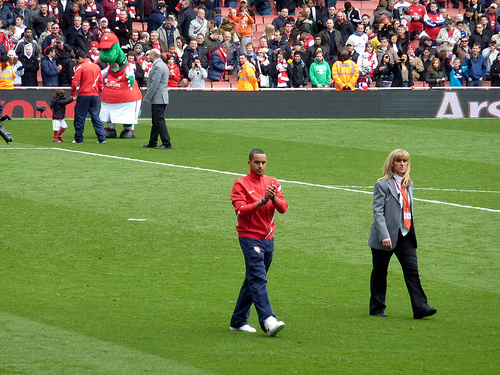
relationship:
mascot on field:
[96, 28, 144, 135] [296, 123, 338, 143]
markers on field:
[192, 161, 219, 176] [296, 123, 338, 143]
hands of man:
[265, 186, 278, 200] [229, 138, 296, 329]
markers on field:
[0, 147, 500, 213] [296, 123, 338, 143]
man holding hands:
[229, 138, 296, 329] [265, 186, 278, 200]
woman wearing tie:
[368, 154, 423, 322] [404, 196, 415, 206]